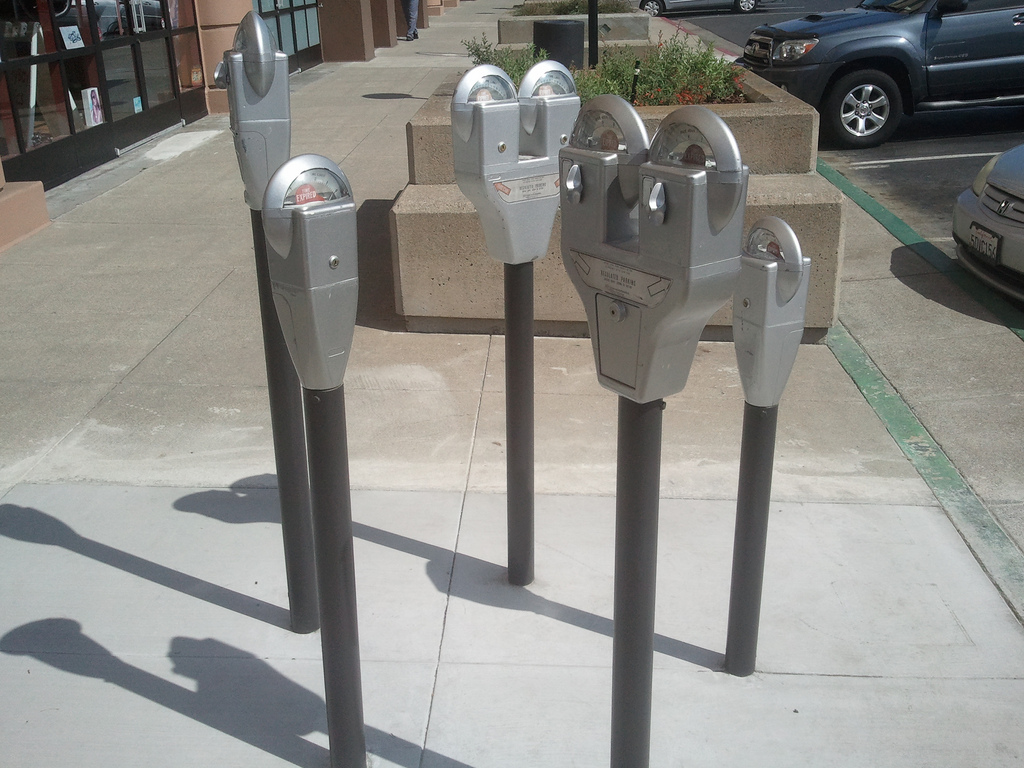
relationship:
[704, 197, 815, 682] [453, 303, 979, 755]
parking meter on sidewalk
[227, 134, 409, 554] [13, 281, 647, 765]
parking meter on sidewalk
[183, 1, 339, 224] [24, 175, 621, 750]
parking meter on sidewalk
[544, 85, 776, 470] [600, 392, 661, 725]
parking meter on pole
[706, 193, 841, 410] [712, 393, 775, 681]
parking meter on pole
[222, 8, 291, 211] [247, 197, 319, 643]
parking meter on pole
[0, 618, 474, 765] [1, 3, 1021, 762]
shadow on ground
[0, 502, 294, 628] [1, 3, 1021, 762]
shadow on ground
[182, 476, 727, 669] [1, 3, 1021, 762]
shadow on ground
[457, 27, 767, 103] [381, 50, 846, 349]
plants in planter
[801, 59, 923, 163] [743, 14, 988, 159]
tire on car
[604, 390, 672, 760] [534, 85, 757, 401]
pole under meter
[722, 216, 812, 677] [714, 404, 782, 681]
parking meter has metal pole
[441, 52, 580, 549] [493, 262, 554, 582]
parking meter has metal pole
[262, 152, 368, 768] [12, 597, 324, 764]
parking meter has shadow